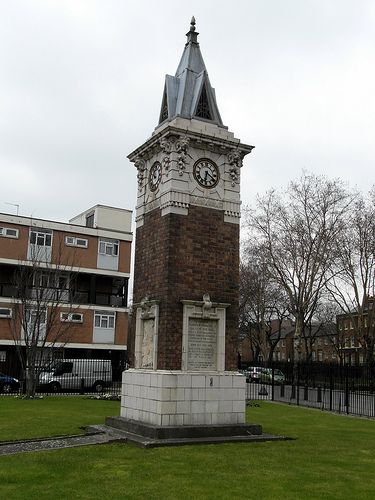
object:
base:
[118, 370, 247, 425]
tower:
[105, 16, 263, 441]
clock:
[192, 155, 219, 189]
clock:
[147, 161, 162, 192]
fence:
[273, 369, 375, 418]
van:
[38, 359, 113, 393]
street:
[0, 387, 123, 393]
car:
[0, 377, 23, 391]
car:
[259, 366, 287, 387]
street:
[245, 381, 375, 417]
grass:
[0, 395, 375, 499]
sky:
[0, 0, 375, 324]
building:
[0, 202, 133, 394]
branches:
[344, 286, 357, 313]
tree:
[320, 186, 375, 391]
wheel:
[95, 381, 107, 393]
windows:
[5, 226, 18, 237]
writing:
[187, 316, 218, 370]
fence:
[0, 356, 125, 398]